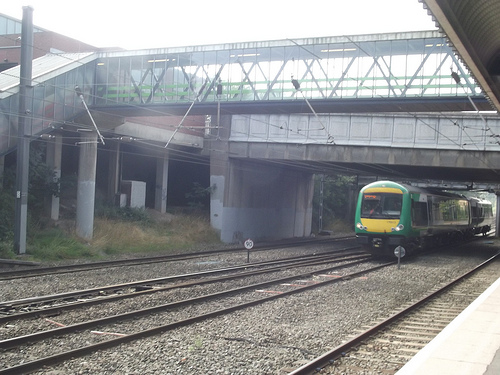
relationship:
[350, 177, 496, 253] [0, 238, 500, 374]
train on tracks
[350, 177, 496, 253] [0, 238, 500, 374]
train next to tracks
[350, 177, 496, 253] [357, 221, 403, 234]
train has headlights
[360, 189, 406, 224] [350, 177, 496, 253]
windshield on train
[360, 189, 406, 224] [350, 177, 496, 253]
windshield of train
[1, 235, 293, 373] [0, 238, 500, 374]
three of four train tracks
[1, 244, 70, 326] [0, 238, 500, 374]
two of four train tracks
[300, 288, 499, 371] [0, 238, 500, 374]
one of four train tracks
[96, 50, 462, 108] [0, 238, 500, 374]
sky-way crossing over four railroad tracks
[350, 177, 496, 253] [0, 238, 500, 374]
yellow and green train on tracks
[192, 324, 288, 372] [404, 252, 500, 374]
gravel rock between third fourth tracks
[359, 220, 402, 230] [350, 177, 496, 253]
yellow and green train on rails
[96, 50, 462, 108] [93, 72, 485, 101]
walkway with green railing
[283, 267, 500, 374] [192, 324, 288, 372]
two train tracks and gravel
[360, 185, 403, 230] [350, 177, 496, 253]
yellow and green face of train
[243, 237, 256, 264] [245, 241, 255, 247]
metal sign and white face with black lettering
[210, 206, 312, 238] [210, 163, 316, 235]
gray blue wall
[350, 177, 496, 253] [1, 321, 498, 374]
train track has two rails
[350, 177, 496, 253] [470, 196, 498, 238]
train has second car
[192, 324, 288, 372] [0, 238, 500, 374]
gravel between tracks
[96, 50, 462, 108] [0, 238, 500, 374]
walkway above tracks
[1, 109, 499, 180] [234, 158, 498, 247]
hanging wires from top of tunnel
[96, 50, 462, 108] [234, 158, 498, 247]
walkway over tunnel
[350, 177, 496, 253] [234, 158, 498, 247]
train going through underpass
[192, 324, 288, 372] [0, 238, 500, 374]
ground has tracks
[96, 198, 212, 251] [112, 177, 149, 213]
grass has electrical box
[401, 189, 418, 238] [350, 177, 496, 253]
green and yellow train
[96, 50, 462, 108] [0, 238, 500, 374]
bridge over tracks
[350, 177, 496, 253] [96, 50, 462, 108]
train under bridge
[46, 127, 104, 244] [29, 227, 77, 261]
pillars have grass underneath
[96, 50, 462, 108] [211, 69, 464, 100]
bridge has people walking